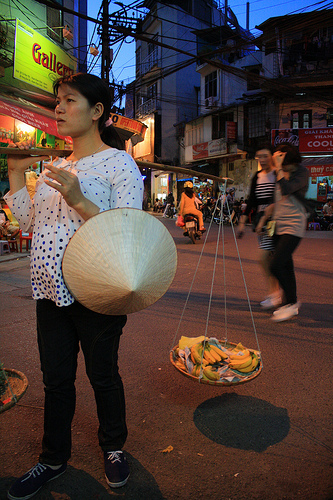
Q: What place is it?
A: It is a street.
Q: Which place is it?
A: It is a street.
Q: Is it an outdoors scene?
A: Yes, it is outdoors.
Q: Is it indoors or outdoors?
A: It is outdoors.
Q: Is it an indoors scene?
A: No, it is outdoors.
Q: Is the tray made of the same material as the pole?
A: Yes, both the tray and the pole are made of wood.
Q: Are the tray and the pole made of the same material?
A: Yes, both the tray and the pole are made of wood.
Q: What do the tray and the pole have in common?
A: The material, both the tray and the pole are wooden.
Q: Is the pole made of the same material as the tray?
A: Yes, both the pole and the tray are made of wood.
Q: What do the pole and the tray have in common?
A: The material, both the pole and the tray are wooden.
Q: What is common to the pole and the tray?
A: The material, both the pole and the tray are wooden.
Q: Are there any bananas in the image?
A: Yes, there are bananas.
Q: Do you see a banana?
A: Yes, there are bananas.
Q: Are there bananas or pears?
A: Yes, there are bananas.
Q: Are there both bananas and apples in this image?
A: No, there are bananas but no apples.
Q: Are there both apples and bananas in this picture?
A: No, there are bananas but no apples.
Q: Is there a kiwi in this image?
A: No, there are no kiwis.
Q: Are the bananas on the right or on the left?
A: The bananas are on the right of the image.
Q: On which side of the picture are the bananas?
A: The bananas are on the right of the image.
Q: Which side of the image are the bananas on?
A: The bananas are on the right of the image.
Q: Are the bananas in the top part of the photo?
A: No, the bananas are in the bottom of the image.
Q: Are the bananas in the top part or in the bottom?
A: The bananas are in the bottom of the image.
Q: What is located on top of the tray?
A: The bananas are on top of the tray.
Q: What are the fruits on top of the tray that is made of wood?
A: The fruits are bananas.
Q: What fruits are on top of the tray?
A: The fruits are bananas.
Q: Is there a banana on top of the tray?
A: Yes, there are bananas on top of the tray.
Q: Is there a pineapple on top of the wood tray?
A: No, there are bananas on top of the tray.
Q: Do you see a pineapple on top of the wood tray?
A: No, there are bananas on top of the tray.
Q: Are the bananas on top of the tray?
A: Yes, the bananas are on top of the tray.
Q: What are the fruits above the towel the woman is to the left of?
A: The fruits are bananas.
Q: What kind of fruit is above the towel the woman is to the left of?
A: The fruits are bananas.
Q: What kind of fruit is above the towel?
A: The fruits are bananas.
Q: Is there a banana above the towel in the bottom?
A: Yes, there are bananas above the towel.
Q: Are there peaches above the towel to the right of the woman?
A: No, there are bananas above the towel.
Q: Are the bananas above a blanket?
A: No, the bananas are above a towel.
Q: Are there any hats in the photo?
A: Yes, there is a hat.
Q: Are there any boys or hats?
A: Yes, there is a hat.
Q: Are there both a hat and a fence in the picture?
A: No, there is a hat but no fences.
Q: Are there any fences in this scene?
A: No, there are no fences.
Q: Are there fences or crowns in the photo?
A: No, there are no fences or crowns.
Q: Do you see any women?
A: Yes, there is a woman.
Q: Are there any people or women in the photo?
A: Yes, there is a woman.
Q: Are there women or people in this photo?
A: Yes, there is a woman.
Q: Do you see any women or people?
A: Yes, there is a woman.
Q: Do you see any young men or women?
A: Yes, there is a young woman.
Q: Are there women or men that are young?
A: Yes, the woman is young.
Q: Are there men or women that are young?
A: Yes, the woman is young.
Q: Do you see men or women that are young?
A: Yes, the woman is young.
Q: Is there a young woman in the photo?
A: Yes, there is a young woman.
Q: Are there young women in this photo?
A: Yes, there is a young woman.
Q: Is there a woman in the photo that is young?
A: Yes, there is a woman that is young.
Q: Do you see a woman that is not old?
A: Yes, there is an young woman.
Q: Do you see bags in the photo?
A: No, there are no bags.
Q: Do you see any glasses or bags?
A: No, there are no bags or glasses.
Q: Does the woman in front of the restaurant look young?
A: Yes, the woman is young.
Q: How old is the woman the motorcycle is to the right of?
A: The woman is young.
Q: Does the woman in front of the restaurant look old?
A: No, the woman is young.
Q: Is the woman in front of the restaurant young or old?
A: The woman is young.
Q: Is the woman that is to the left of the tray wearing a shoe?
A: Yes, the woman is wearing a shoe.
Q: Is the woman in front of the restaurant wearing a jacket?
A: No, the woman is wearing a shoe.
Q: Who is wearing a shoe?
A: The woman is wearing a shoe.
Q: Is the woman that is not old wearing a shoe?
A: Yes, the woman is wearing a shoe.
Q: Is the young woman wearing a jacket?
A: No, the woman is wearing a shoe.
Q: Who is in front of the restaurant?
A: The woman is in front of the restaurant.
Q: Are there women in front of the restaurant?
A: Yes, there is a woman in front of the restaurant.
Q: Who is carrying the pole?
A: The woman is carrying the pole.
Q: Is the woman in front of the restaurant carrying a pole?
A: Yes, the woman is carrying a pole.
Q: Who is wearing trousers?
A: The woman is wearing trousers.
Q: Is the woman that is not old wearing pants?
A: Yes, the woman is wearing pants.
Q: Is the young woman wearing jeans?
A: No, the woman is wearing pants.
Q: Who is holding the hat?
A: The woman is holding the hat.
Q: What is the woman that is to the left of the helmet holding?
A: The woman is holding the hat.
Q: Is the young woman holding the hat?
A: Yes, the woman is holding the hat.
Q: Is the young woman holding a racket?
A: No, the woman is holding the hat.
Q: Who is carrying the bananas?
A: The woman is carrying the bananas.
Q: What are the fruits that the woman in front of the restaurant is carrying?
A: The fruits are bananas.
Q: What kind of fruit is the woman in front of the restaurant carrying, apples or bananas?
A: The woman is carrying bananas.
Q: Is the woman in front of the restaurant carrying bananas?
A: Yes, the woman is carrying bananas.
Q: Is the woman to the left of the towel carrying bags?
A: No, the woman is carrying bananas.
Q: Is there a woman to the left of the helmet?
A: Yes, there is a woman to the left of the helmet.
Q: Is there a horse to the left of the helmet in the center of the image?
A: No, there is a woman to the left of the helmet.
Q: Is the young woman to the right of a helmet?
A: No, the woman is to the left of a helmet.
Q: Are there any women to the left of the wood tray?
A: Yes, there is a woman to the left of the tray.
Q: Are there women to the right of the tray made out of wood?
A: No, the woman is to the left of the tray.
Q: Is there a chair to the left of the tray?
A: No, there is a woman to the left of the tray.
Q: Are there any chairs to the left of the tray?
A: No, there is a woman to the left of the tray.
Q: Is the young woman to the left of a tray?
A: Yes, the woman is to the left of a tray.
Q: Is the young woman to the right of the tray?
A: No, the woman is to the left of the tray.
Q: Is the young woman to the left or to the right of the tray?
A: The woman is to the left of the tray.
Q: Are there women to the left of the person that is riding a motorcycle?
A: Yes, there is a woman to the left of the person.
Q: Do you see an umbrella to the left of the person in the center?
A: No, there is a woman to the left of the person.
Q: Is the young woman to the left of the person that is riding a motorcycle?
A: Yes, the woman is to the left of the person.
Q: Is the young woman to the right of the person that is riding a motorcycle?
A: No, the woman is to the left of the person.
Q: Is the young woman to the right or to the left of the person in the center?
A: The woman is to the left of the person.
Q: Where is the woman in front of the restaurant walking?
A: The woman is walking on the street.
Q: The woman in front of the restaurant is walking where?
A: The woman is walking on the street.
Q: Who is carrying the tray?
A: The woman is carrying the tray.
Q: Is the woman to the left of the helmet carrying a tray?
A: Yes, the woman is carrying a tray.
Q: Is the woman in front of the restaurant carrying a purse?
A: No, the woman is carrying a tray.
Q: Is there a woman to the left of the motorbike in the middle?
A: Yes, there is a woman to the left of the motorcycle.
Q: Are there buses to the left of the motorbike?
A: No, there is a woman to the left of the motorbike.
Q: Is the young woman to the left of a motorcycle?
A: Yes, the woman is to the left of a motorcycle.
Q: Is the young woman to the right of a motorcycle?
A: No, the woman is to the left of a motorcycle.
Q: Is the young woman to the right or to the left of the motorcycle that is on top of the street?
A: The woman is to the left of the motorbike.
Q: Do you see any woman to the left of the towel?
A: Yes, there is a woman to the left of the towel.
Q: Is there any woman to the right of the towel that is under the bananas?
A: No, the woman is to the left of the towel.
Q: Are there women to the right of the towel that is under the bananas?
A: No, the woman is to the left of the towel.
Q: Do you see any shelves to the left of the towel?
A: No, there is a woman to the left of the towel.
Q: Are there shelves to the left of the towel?
A: No, there is a woman to the left of the towel.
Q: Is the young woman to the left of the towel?
A: Yes, the woman is to the left of the towel.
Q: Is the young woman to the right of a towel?
A: No, the woman is to the left of a towel.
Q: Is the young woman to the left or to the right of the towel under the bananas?
A: The woman is to the left of the towel.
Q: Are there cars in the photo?
A: No, there are no cars.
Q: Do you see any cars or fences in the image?
A: No, there are no cars or fences.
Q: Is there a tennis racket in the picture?
A: No, there are no rackets.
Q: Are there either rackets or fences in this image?
A: No, there are no rackets or fences.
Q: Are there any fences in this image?
A: No, there are no fences.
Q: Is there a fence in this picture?
A: No, there are no fences.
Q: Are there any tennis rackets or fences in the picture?
A: No, there are no fences or tennis rackets.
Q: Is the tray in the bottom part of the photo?
A: Yes, the tray is in the bottom of the image.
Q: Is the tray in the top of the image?
A: No, the tray is in the bottom of the image.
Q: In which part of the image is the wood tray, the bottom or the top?
A: The tray is in the bottom of the image.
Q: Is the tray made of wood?
A: Yes, the tray is made of wood.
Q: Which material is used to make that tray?
A: The tray is made of wood.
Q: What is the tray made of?
A: The tray is made of wood.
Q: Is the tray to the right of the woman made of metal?
A: No, the tray is made of wood.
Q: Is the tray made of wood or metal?
A: The tray is made of wood.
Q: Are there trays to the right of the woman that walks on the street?
A: Yes, there is a tray to the right of the woman.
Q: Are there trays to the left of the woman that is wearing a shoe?
A: No, the tray is to the right of the woman.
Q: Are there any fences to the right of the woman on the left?
A: No, there is a tray to the right of the woman.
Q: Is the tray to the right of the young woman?
A: Yes, the tray is to the right of the woman.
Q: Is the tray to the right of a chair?
A: No, the tray is to the right of the woman.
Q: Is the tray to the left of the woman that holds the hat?
A: No, the tray is to the right of the woman.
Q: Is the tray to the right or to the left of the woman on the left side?
A: The tray is to the right of the woman.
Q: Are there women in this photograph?
A: Yes, there is a woman.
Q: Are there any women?
A: Yes, there is a woman.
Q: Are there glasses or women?
A: Yes, there is a woman.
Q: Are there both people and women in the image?
A: Yes, there are both a woman and a person.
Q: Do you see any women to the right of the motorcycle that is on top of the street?
A: Yes, there is a woman to the right of the motorcycle.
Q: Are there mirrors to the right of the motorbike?
A: No, there is a woman to the right of the motorbike.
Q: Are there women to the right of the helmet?
A: Yes, there is a woman to the right of the helmet.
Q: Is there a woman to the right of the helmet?
A: Yes, there is a woman to the right of the helmet.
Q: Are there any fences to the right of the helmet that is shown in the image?
A: No, there is a woman to the right of the helmet.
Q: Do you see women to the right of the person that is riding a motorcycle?
A: Yes, there is a woman to the right of the person.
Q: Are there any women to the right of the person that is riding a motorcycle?
A: Yes, there is a woman to the right of the person.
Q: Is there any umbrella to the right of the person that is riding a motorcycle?
A: No, there is a woman to the right of the person.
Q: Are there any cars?
A: No, there are no cars.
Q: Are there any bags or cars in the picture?
A: No, there are no cars or bags.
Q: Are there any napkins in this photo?
A: No, there are no napkins.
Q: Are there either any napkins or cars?
A: No, there are no napkins or cars.